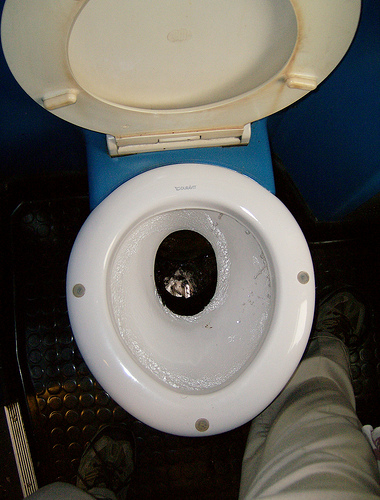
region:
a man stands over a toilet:
[22, 174, 364, 483]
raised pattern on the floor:
[32, 371, 83, 409]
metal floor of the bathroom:
[1, 366, 63, 473]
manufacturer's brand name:
[168, 179, 201, 187]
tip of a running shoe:
[76, 418, 136, 469]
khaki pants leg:
[281, 393, 357, 488]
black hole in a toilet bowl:
[152, 224, 221, 314]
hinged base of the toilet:
[87, 130, 272, 163]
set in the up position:
[7, 5, 363, 150]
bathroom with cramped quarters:
[12, 118, 373, 433]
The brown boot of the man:
[317, 280, 368, 351]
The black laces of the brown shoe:
[78, 440, 139, 492]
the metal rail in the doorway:
[4, 406, 36, 498]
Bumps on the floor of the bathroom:
[13, 198, 60, 404]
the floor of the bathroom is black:
[13, 208, 65, 424]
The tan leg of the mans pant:
[286, 333, 378, 498]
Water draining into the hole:
[125, 218, 244, 341]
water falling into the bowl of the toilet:
[237, 252, 266, 320]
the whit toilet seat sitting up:
[0, 1, 377, 172]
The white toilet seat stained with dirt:
[56, 0, 328, 159]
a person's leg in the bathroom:
[234, 338, 378, 498]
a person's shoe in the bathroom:
[53, 420, 159, 494]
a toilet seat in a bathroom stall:
[60, 165, 310, 435]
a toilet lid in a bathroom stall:
[1, 2, 368, 163]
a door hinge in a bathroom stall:
[1, 401, 46, 498]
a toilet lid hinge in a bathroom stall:
[79, 119, 278, 164]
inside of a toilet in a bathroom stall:
[143, 229, 241, 331]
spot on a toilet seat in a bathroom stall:
[286, 266, 314, 295]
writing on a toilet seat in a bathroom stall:
[166, 181, 205, 194]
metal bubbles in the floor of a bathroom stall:
[35, 394, 103, 450]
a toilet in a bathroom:
[3, 9, 378, 486]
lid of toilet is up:
[5, 2, 363, 157]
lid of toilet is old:
[4, 6, 368, 158]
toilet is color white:
[58, 157, 314, 449]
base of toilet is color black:
[146, 225, 233, 336]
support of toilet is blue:
[74, 119, 295, 250]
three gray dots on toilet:
[65, 263, 310, 438]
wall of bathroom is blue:
[9, 64, 378, 212]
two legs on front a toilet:
[22, 285, 378, 498]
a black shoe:
[65, 407, 144, 496]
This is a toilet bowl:
[102, 213, 242, 370]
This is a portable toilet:
[64, 182, 359, 392]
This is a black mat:
[7, 328, 113, 454]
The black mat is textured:
[21, 383, 110, 470]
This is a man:
[318, 403, 346, 489]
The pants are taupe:
[292, 422, 331, 476]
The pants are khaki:
[279, 412, 328, 483]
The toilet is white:
[66, 258, 288, 415]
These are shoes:
[314, 309, 378, 349]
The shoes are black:
[75, 442, 121, 482]